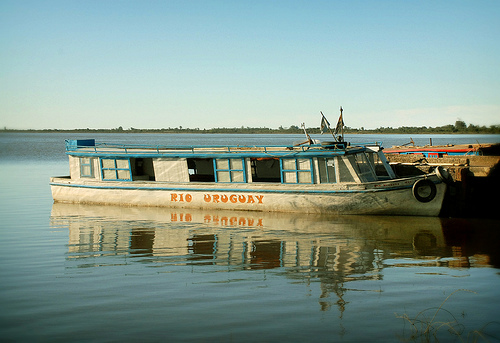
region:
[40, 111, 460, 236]
boat on the water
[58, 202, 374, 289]
reflection in the water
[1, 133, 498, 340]
calm body of water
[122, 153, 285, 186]
three windows on the boat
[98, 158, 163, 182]
window is open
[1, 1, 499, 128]
blue sky with no clouds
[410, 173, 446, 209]
round black life preserver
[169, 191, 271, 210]
orange writing on the side of the boat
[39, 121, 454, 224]
blue and white boat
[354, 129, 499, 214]
pier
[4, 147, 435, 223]
house boat in water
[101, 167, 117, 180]
pane in the window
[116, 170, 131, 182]
pane in the window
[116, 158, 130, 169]
pane in the window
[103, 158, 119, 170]
pane in the window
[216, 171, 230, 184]
pane in the window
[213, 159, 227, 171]
pane in the window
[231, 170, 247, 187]
pane in the window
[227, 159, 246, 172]
pane in the window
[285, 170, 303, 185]
pane in the window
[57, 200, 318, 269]
a reflection of a boat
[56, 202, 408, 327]
a reflection of a boat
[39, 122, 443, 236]
the boat is white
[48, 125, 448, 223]
A boat sits in the water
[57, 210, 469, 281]
The reflection of a boat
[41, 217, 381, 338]
The water is calm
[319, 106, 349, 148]
Two flags on the boat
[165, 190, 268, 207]
Orange lettering on the boat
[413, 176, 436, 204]
A tire on a boat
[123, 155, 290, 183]
Three open windows on the boat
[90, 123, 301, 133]
Trees in the distance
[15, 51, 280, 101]
There are no clouds in the sky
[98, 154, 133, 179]
Four window panes in one window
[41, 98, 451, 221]
a boat on body of water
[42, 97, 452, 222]
boat call "Rio Uruguay"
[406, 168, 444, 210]
a tire in front a boat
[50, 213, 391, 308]
the reflection of a boat on water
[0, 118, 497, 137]
trees on the shore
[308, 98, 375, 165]
two small flags on the boat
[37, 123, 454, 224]
boat is blue and white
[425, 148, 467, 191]
a tire on nose of boat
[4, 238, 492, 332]
ripples formed in the water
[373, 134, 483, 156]
a red roof